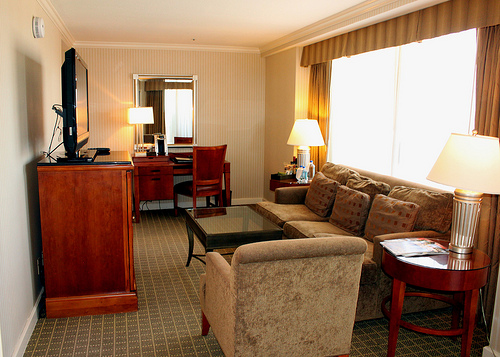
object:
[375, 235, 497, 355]
end table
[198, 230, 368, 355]
chair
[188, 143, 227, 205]
chair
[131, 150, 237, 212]
desk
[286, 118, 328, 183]
lamp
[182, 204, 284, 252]
coffee table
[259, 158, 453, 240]
sofa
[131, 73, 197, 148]
mirror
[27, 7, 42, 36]
smoke alarm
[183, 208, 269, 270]
trim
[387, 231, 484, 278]
wooden table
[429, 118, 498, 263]
lamp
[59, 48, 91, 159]
tv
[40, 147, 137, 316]
console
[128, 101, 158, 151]
lamp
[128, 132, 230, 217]
desk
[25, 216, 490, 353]
carpet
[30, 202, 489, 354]
floor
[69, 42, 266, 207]
wall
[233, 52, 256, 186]
wallpaper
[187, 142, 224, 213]
chair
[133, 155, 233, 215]
desk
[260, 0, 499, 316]
wall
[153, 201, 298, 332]
carpet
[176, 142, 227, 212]
chair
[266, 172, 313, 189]
end table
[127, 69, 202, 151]
mirror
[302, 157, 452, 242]
pillows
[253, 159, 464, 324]
couch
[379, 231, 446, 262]
magazine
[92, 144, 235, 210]
table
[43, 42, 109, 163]
television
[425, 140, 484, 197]
shade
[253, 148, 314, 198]
objects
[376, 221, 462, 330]
table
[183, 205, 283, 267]
table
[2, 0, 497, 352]
room